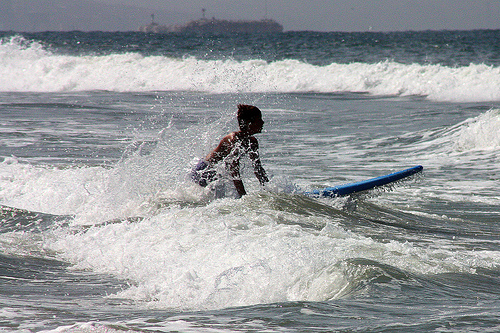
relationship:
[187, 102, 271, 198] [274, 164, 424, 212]
boy in surfboard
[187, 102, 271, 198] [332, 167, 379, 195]
boy riding a surfboard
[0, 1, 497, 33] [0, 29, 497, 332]
sky over ocean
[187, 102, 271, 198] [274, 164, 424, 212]
boy on surfboard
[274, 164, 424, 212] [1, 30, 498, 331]
surfboard on water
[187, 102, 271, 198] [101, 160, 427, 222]
boy riding a surfboard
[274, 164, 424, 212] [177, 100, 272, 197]
surfboard with a man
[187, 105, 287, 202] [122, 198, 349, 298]
boy riding wave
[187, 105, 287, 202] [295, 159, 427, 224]
boy on surfboard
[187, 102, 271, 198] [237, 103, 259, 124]
boy with hair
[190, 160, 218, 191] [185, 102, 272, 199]
suit worn by boy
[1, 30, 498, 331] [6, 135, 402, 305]
water by wave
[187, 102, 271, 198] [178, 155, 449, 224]
boy on surfbaord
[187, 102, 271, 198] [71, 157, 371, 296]
boy riding wave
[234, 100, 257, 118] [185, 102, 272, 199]
hair on boy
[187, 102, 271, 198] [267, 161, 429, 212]
boy on surfboard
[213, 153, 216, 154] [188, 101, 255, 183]
skin on boy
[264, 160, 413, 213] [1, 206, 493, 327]
surfboard in water